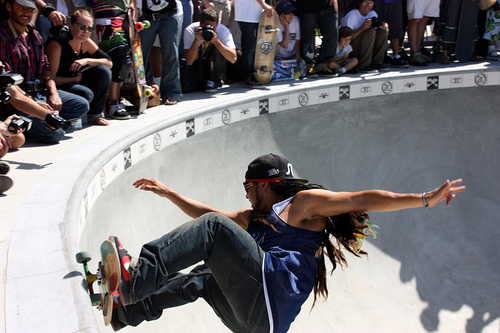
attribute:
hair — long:
[266, 172, 381, 318]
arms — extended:
[138, 169, 463, 219]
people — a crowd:
[1, 1, 494, 187]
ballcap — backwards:
[243, 152, 308, 184]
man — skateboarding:
[68, 147, 465, 326]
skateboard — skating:
[70, 236, 123, 328]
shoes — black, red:
[65, 234, 165, 328]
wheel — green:
[71, 237, 121, 315]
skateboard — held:
[244, 9, 286, 86]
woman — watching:
[40, 21, 138, 106]